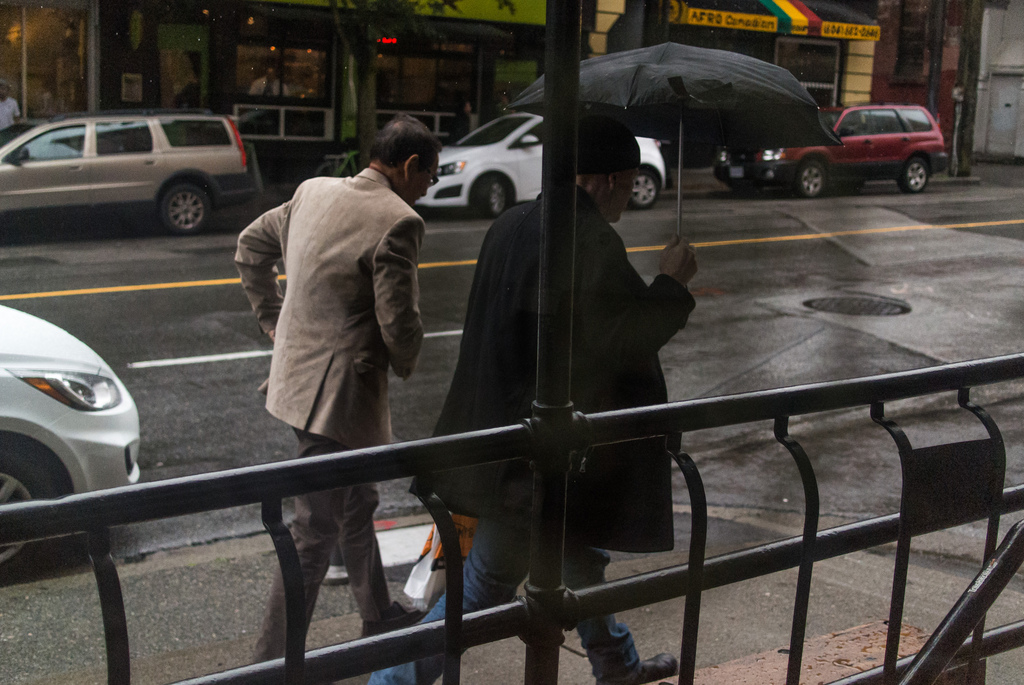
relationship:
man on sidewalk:
[379, 116, 700, 683] [10, 385, 1011, 681]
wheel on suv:
[161, 191, 214, 233] [713, 96, 940, 198]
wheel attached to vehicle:
[1, 435, 88, 576] [5, 292, 155, 588]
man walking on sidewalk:
[379, 116, 700, 683] [119, 536, 878, 681]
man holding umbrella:
[463, 83, 697, 604] [577, 29, 833, 306]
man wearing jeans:
[379, 116, 700, 683] [431, 515, 648, 680]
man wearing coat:
[463, 145, 693, 649] [431, 186, 671, 521]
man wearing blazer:
[247, 117, 420, 649] [225, 158, 403, 452]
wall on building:
[62, 39, 741, 191] [93, 31, 912, 297]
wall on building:
[155, 26, 570, 307] [39, 24, 856, 266]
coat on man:
[243, 225, 395, 364] [210, 95, 502, 471]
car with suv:
[401, 78, 719, 228] [720, 117, 1004, 208]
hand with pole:
[580, 184, 766, 329] [658, 136, 715, 242]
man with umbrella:
[379, 116, 700, 683] [638, 16, 865, 183]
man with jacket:
[247, 117, 420, 649] [401, 219, 713, 546]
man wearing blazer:
[247, 117, 420, 649] [239, 168, 426, 453]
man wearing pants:
[247, 117, 420, 649] [252, 430, 425, 657]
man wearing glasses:
[247, 117, 420, 649] [423, 167, 447, 191]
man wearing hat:
[379, 116, 700, 683] [565, 108, 639, 163]